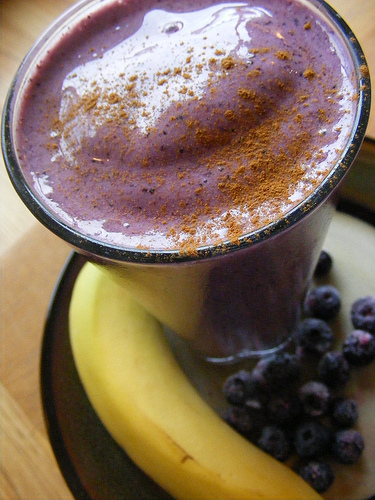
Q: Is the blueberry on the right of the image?
A: Yes, the blueberry is on the right of the image.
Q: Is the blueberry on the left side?
A: No, the blueberry is on the right of the image.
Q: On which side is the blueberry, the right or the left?
A: The blueberry is on the right of the image.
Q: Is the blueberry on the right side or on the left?
A: The blueberry is on the right of the image.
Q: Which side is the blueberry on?
A: The blueberry is on the right of the image.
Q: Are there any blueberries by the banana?
A: Yes, there is a blueberry by the banana.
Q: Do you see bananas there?
A: Yes, there is a banana.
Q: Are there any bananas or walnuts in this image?
A: Yes, there is a banana.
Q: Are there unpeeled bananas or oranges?
A: Yes, there is an unpeeled banana.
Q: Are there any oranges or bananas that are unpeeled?
A: Yes, the banana is unpeeled.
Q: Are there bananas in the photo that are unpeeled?
A: Yes, there is an unpeeled banana.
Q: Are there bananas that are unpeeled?
A: Yes, there is a banana that is unpeeled.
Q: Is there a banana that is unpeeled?
A: Yes, there is a banana that is unpeeled.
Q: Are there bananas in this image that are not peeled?
A: Yes, there is a unpeeled banana.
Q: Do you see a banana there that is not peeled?
A: Yes, there is a unpeeled banana.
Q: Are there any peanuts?
A: No, there are no peanuts.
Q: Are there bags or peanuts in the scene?
A: No, there are no peanuts or bags.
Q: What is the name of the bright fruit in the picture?
A: The fruit is a banana.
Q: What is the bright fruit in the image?
A: The fruit is a banana.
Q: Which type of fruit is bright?
A: The fruit is a banana.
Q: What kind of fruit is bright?
A: The fruit is a banana.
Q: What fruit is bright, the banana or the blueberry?
A: The banana is bright.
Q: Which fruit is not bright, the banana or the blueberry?
A: The blueberry is not bright.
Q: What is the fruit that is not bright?
A: The fruit is a blueberry.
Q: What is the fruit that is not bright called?
A: The fruit is a blueberry.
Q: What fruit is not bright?
A: The fruit is a blueberry.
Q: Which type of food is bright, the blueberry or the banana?
A: The banana is bright.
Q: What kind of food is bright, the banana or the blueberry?
A: The banana is bright.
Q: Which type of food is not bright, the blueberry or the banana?
A: The blueberry is not bright.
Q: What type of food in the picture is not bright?
A: The food is a blueberry.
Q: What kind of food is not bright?
A: The food is a blueberry.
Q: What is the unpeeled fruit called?
A: The fruit is a banana.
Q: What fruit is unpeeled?
A: The fruit is a banana.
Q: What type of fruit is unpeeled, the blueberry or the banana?
A: The banana is unpeeled.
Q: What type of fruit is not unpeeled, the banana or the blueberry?
A: The blueberry is not unpeeled.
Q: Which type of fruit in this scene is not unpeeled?
A: The fruit is a blueberry.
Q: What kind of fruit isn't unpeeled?
A: The fruit is a blueberry.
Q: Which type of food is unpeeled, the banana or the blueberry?
A: The banana is unpeeled.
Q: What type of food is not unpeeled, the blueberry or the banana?
A: The blueberry is not unpeeled.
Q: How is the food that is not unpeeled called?
A: The food is a blueberry.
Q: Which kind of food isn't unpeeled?
A: The food is a blueberry.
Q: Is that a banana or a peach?
A: That is a banana.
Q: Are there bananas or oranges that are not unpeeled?
A: No, there is a banana but it is unpeeled.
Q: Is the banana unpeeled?
A: Yes, the banana is unpeeled.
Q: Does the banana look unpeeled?
A: Yes, the banana is unpeeled.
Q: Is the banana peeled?
A: No, the banana is unpeeled.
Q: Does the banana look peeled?
A: No, the banana is unpeeled.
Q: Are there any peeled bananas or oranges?
A: No, there is a banana but it is unpeeled.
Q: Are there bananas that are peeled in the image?
A: No, there is a banana but it is unpeeled.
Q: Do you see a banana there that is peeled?
A: No, there is a banana but it is unpeeled.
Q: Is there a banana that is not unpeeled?
A: No, there is a banana but it is unpeeled.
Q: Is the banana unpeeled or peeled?
A: The banana is unpeeled.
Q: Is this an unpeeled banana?
A: Yes, this is an unpeeled banana.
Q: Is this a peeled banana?
A: No, this is an unpeeled banana.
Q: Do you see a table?
A: Yes, there is a table.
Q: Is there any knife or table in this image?
A: Yes, there is a table.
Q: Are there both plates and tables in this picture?
A: Yes, there are both a table and a plate.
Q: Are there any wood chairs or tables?
A: Yes, there is a wood table.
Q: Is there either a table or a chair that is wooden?
A: Yes, the table is wooden.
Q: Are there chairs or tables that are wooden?
A: Yes, the table is wooden.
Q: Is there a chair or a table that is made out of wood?
A: Yes, the table is made of wood.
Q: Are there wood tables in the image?
A: Yes, there is a wood table.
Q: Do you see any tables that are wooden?
A: Yes, there is a table that is wooden.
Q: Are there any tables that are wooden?
A: Yes, there is a table that is wooden.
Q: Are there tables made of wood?
A: Yes, there is a table that is made of wood.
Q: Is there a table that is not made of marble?
A: Yes, there is a table that is made of wood.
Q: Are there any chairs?
A: No, there are no chairs.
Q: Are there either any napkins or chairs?
A: No, there are no chairs or napkins.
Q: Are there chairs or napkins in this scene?
A: No, there are no chairs or napkins.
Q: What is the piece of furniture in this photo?
A: The piece of furniture is a table.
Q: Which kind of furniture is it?
A: The piece of furniture is a table.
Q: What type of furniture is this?
A: This is a table.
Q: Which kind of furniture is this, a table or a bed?
A: This is a table.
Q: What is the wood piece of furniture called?
A: The piece of furniture is a table.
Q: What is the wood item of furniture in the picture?
A: The piece of furniture is a table.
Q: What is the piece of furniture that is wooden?
A: The piece of furniture is a table.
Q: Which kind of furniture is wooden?
A: The furniture is a table.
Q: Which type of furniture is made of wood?
A: The furniture is a table.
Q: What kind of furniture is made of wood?
A: The furniture is a table.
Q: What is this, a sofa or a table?
A: This is a table.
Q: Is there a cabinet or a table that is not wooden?
A: No, there is a table but it is wooden.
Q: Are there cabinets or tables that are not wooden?
A: No, there is a table but it is wooden.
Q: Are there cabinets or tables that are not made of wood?
A: No, there is a table but it is made of wood.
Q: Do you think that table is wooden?
A: Yes, the table is wooden.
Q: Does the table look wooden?
A: Yes, the table is wooden.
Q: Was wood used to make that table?
A: Yes, the table is made of wood.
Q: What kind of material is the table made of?
A: The table is made of wood.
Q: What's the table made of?
A: The table is made of wood.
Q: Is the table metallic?
A: No, the table is wooden.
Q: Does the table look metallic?
A: No, the table is wooden.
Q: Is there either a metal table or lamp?
A: No, there is a table but it is wooden.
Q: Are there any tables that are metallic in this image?
A: No, there is a table but it is wooden.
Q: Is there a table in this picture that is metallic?
A: No, there is a table but it is wooden.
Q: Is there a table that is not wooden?
A: No, there is a table but it is wooden.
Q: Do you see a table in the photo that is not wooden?
A: No, there is a table but it is wooden.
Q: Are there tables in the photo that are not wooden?
A: No, there is a table but it is wooden.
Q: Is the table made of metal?
A: No, the table is made of wood.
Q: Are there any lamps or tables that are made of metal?
A: No, there is a table but it is made of wood.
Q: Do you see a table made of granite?
A: No, there is a table but it is made of wood.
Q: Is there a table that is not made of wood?
A: No, there is a table but it is made of wood.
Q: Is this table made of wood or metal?
A: The table is made of wood.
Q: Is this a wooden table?
A: Yes, this is a wooden table.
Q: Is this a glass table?
A: No, this is a wooden table.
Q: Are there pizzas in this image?
A: No, there are no pizzas.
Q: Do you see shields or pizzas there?
A: No, there are no pizzas or shields.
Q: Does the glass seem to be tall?
A: Yes, the glass is tall.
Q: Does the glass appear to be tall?
A: Yes, the glass is tall.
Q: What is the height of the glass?
A: The glass is tall.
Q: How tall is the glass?
A: The glass is tall.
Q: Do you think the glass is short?
A: No, the glass is tall.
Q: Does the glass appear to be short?
A: No, the glass is tall.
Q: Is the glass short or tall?
A: The glass is tall.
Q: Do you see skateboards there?
A: No, there are no skateboards.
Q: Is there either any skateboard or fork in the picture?
A: No, there are no skateboards or forks.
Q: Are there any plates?
A: Yes, there is a plate.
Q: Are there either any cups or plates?
A: Yes, there is a plate.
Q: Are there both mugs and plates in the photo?
A: No, there is a plate but no mugs.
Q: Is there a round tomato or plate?
A: Yes, there is a round plate.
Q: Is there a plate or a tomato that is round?
A: Yes, the plate is round.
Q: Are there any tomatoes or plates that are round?
A: Yes, the plate is round.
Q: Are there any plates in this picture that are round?
A: Yes, there is a round plate.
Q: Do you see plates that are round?
A: Yes, there is a round plate.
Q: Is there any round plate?
A: Yes, there is a round plate.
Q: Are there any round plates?
A: Yes, there is a round plate.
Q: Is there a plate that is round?
A: Yes, there is a plate that is round.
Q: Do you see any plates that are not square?
A: Yes, there is a round plate.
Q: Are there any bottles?
A: No, there are no bottles.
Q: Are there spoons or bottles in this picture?
A: No, there are no bottles or spoons.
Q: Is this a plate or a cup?
A: This is a plate.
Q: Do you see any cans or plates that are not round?
A: No, there is a plate but it is round.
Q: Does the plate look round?
A: Yes, the plate is round.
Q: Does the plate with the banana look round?
A: Yes, the plate is round.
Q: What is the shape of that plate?
A: The plate is round.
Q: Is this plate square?
A: No, the plate is round.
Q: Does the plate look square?
A: No, the plate is round.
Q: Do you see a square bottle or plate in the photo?
A: No, there is a plate but it is round.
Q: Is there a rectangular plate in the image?
A: No, there is a plate but it is round.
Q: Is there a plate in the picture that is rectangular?
A: No, there is a plate but it is round.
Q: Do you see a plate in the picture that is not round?
A: No, there is a plate but it is round.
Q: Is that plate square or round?
A: The plate is round.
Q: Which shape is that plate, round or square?
A: The plate is round.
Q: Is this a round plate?
A: Yes, this is a round plate.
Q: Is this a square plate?
A: No, this is a round plate.